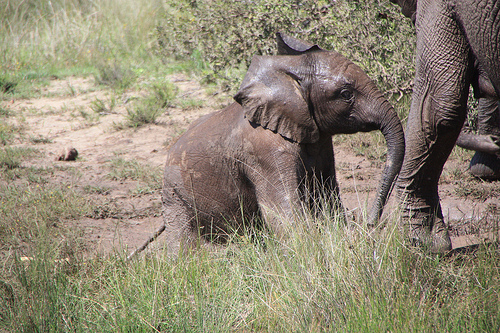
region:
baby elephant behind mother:
[132, 40, 411, 251]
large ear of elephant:
[232, 67, 314, 147]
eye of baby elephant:
[328, 82, 356, 113]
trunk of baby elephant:
[361, 118, 396, 233]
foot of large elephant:
[398, 187, 449, 252]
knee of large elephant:
[423, 107, 460, 154]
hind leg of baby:
[152, 200, 209, 255]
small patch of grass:
[89, 96, 119, 112]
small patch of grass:
[117, 105, 158, 130]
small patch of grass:
[173, 94, 203, 114]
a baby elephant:
[116, 26, 406, 265]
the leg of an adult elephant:
[393, 1, 475, 256]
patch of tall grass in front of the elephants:
[0, 148, 497, 331]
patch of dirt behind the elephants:
[6, 66, 497, 261]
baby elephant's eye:
[334, 81, 356, 102]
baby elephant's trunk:
[355, 86, 405, 226]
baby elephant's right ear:
[233, 52, 323, 144]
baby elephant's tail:
[108, 221, 173, 265]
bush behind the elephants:
[152, 1, 422, 107]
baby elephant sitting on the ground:
[150, 28, 408, 257]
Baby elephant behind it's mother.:
[119, 25, 413, 235]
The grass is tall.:
[168, 247, 436, 331]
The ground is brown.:
[41, 97, 128, 154]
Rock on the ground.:
[41, 132, 101, 171]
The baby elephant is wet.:
[168, 41, 430, 257]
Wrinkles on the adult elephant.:
[404, 5, 479, 255]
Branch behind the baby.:
[111, 214, 163, 264]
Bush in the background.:
[198, 1, 434, 93]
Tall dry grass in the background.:
[13, 7, 145, 52]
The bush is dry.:
[333, 5, 408, 72]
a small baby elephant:
[160, 26, 407, 257]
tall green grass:
[345, 168, 411, 331]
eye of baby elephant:
[337, 85, 352, 100]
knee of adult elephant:
[420, 82, 463, 137]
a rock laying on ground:
[48, 142, 79, 164]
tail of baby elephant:
[115, 215, 163, 271]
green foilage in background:
[142, 0, 419, 91]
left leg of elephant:
[467, 91, 499, 185]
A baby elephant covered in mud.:
[156, 19, 402, 256]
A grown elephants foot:
[402, 3, 479, 257]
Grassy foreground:
[4, 0, 164, 330]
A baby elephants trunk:
[358, 77, 407, 236]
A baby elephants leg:
[241, 131, 316, 251]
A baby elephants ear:
[235, 59, 323, 150]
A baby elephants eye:
[327, 82, 357, 102]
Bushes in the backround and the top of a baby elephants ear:
[153, 0, 418, 52]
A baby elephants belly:
[185, 170, 267, 255]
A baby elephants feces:
[52, 131, 92, 173]